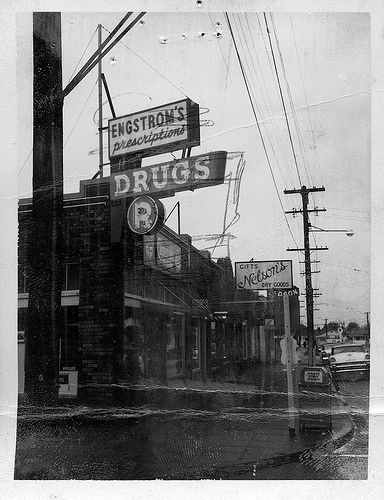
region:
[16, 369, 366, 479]
this old photograph has significant damage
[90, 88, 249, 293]
this old photo needs major photoshopping to eliminate the scribbling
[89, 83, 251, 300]
somebody scribbled all over this picture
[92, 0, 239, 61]
apparently someone has thrown darts at this photo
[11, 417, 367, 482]
there are a lot of fingerprints on this photo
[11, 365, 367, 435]
this photo has been folded in a couple of places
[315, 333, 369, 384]
vintage cars in this vintage photo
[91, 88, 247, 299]
an old fashioned sign for Engstrom's prescriptions and Drug store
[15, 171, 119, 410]
this building has brick facing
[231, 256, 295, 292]
a sign for Nelson's Dry Good and Gifts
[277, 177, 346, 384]
the pole is tall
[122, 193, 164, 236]
the sign is round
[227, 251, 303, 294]
the sign is rectangular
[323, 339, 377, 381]
the car is parked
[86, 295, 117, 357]
the wall is made of brick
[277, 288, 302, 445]
the pole is in the sidewalk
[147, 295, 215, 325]
the awning is attached to the building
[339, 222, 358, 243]
the streetlight is off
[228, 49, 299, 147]
the wires are above the sidewalk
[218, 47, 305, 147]
the wires are black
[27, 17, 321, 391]
utility poles along the sidewalk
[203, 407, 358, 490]
curb of the sidewalk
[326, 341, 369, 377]
white car parked on street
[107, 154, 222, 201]
sign with white lettering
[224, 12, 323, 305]
power lines running between utility poles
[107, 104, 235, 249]
two business signs on the same pole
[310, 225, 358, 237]
street light attached to utility pole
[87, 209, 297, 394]
storefronts along the sidewalk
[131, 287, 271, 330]
canopies over the sidewalk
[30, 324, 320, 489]
sidewalk in front of storefronts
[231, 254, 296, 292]
The sign is rectangular.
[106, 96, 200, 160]
The sign is rectangular.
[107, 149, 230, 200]
The sign is rectangular.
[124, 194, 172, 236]
The sign is round.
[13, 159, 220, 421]
The building is bricked.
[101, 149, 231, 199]
The sign is neon.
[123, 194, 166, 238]
The sign is neon.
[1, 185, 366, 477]
The street is flooded.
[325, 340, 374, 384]
The car is parked.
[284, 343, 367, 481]
The container is near the curb of the street.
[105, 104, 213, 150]
Black writing on sign.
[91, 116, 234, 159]
White sign attached to pole.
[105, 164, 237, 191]
White writing on sign.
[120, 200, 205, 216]
White letter R on sign.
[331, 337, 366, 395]
White car parked on street.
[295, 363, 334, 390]
Sign on side of sidewalk.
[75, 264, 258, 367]
Brick buildings on side of road.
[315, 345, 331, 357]
White car on side of road.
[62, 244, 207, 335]
Building is made from brick.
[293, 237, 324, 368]
Telephone poles line sidewalk.